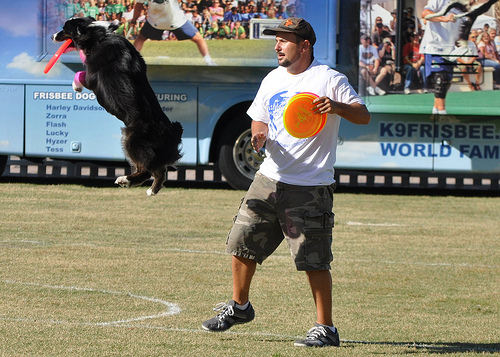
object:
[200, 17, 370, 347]
man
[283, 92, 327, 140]
frisbee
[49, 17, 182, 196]
dog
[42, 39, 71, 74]
frisbee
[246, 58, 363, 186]
shirt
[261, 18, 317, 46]
cap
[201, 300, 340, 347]
shoes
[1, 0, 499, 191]
bus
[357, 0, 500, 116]
picture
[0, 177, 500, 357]
playground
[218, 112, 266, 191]
wheel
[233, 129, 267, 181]
hub cap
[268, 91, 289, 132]
lettering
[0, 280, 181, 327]
lines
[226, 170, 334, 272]
shorts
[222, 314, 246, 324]
stripes